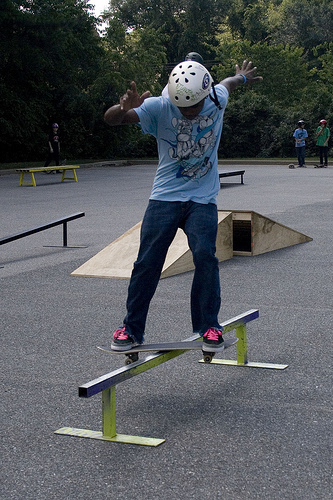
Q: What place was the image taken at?
A: It was taken at the road.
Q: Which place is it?
A: It is a road.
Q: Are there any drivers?
A: No, there are no drivers.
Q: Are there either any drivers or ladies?
A: No, there are no drivers or ladies.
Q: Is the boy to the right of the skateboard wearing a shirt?
A: Yes, the boy is wearing a shirt.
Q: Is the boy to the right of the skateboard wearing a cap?
A: No, the boy is wearing a shirt.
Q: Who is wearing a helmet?
A: The boy is wearing a helmet.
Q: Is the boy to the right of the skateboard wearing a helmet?
A: Yes, the boy is wearing a helmet.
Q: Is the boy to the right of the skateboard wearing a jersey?
A: No, the boy is wearing a helmet.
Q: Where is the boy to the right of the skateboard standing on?
A: The boy is standing on the floor.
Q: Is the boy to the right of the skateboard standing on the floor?
A: Yes, the boy is standing on the floor.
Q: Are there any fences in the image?
A: No, there are no fences.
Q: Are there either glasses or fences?
A: No, there are no fences or glasses.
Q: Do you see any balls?
A: No, there are no balls.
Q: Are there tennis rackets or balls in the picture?
A: No, there are no balls or tennis rackets.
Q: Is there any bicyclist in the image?
A: No, there are no cyclists.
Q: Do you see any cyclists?
A: No, there are no cyclists.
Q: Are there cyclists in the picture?
A: No, there are no cyclists.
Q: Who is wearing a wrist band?
A: The boy is wearing a wrist band.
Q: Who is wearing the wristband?
A: The boy is wearing a wrist band.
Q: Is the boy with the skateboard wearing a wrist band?
A: Yes, the boy is wearing a wrist band.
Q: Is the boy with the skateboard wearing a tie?
A: No, the boy is wearing a wrist band.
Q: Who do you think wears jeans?
A: The boy wears jeans.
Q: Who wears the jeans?
A: The boy wears jeans.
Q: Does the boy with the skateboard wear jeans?
A: Yes, the boy wears jeans.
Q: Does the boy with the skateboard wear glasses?
A: No, the boy wears jeans.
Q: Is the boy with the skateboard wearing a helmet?
A: Yes, the boy is wearing a helmet.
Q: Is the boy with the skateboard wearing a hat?
A: No, the boy is wearing a helmet.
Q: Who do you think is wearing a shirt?
A: The boy is wearing a shirt.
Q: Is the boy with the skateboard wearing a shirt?
A: Yes, the boy is wearing a shirt.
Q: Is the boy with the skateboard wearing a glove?
A: No, the boy is wearing a shirt.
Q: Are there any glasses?
A: No, there are no glasses.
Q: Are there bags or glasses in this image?
A: No, there are no glasses or bags.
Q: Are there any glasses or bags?
A: No, there are no glasses or bags.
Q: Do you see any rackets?
A: No, there are no rackets.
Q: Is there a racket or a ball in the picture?
A: No, there are no rackets or balls.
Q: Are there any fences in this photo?
A: No, there are no fences.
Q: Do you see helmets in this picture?
A: Yes, there is a helmet.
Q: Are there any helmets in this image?
A: Yes, there is a helmet.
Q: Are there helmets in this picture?
A: Yes, there is a helmet.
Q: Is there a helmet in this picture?
A: Yes, there is a helmet.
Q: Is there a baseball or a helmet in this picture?
A: Yes, there is a helmet.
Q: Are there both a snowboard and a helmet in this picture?
A: No, there is a helmet but no snowboards.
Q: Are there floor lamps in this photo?
A: No, there are no floor lamps.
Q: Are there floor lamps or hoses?
A: No, there are no floor lamps or hoses.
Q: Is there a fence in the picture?
A: No, there are no fences.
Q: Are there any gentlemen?
A: No, there are no gentlemen.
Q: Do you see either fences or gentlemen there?
A: No, there are no gentlemen or fences.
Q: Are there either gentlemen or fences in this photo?
A: No, there are no gentlemen or fences.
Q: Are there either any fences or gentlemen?
A: No, there are no gentlemen or fences.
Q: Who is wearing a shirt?
A: The boy is wearing a shirt.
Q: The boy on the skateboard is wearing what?
A: The boy is wearing a shirt.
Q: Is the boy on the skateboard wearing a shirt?
A: Yes, the boy is wearing a shirt.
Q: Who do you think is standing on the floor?
A: The boy is standing on the floor.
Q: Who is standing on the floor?
A: The boy is standing on the floor.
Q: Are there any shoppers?
A: No, there are no shoppers.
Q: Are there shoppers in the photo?
A: No, there are no shoppers.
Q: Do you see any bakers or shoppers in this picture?
A: No, there are no shoppers or bakers.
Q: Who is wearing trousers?
A: The boy is wearing trousers.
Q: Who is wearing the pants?
A: The boy is wearing trousers.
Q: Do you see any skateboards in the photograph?
A: Yes, there is a skateboard.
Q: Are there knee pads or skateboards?
A: Yes, there is a skateboard.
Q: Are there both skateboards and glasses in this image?
A: No, there is a skateboard but no glasses.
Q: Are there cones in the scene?
A: No, there are no cones.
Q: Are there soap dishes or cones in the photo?
A: No, there are no cones or soap dishes.